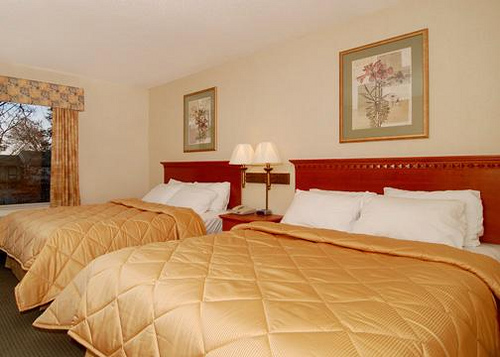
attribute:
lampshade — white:
[252, 141, 283, 164]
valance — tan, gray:
[0, 74, 85, 112]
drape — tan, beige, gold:
[51, 106, 80, 208]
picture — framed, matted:
[338, 28, 429, 143]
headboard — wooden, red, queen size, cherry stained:
[287, 155, 499, 246]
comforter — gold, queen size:
[32, 220, 498, 357]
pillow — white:
[353, 192, 466, 253]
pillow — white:
[281, 190, 364, 235]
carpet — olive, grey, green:
[1, 266, 86, 356]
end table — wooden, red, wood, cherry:
[219, 213, 283, 232]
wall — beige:
[150, 1, 499, 193]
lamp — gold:
[251, 141, 282, 190]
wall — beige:
[0, 58, 149, 217]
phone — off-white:
[231, 205, 256, 216]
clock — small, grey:
[256, 209, 272, 216]